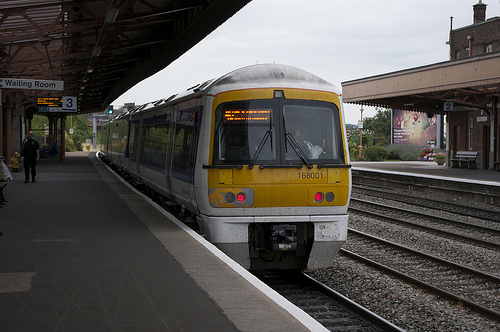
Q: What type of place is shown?
A: It is a station.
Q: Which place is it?
A: It is a station.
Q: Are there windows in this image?
A: Yes, there is a window.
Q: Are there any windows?
A: Yes, there is a window.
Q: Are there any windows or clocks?
A: Yes, there is a window.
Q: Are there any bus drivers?
A: No, there are no bus drivers.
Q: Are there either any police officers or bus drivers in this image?
A: No, there are no bus drivers or police officers.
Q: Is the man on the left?
A: Yes, the man is on the left of the image.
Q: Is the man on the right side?
A: No, the man is on the left of the image.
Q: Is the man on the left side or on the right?
A: The man is on the left of the image.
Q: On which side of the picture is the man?
A: The man is on the left of the image.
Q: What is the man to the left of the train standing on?
A: The man is standing on the platform.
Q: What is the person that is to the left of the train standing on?
A: The man is standing on the platform.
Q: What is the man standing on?
A: The man is standing on the platform.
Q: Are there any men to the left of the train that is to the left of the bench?
A: Yes, there is a man to the left of the train.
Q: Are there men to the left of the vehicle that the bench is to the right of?
A: Yes, there is a man to the left of the train.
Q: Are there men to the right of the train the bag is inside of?
A: No, the man is to the left of the train.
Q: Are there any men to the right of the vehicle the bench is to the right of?
A: No, the man is to the left of the train.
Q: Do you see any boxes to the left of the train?
A: No, there is a man to the left of the train.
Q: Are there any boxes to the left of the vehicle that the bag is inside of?
A: No, there is a man to the left of the train.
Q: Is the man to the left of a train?
A: Yes, the man is to the left of a train.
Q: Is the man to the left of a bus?
A: No, the man is to the left of a train.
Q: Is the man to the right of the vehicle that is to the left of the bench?
A: No, the man is to the left of the train.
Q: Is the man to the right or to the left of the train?
A: The man is to the left of the train.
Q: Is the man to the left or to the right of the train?
A: The man is to the left of the train.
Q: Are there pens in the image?
A: No, there are no pens.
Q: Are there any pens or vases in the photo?
A: No, there are no pens or vases.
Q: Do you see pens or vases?
A: No, there are no pens or vases.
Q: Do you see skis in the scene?
A: No, there are no skis.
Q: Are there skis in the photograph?
A: No, there are no skis.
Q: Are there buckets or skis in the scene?
A: No, there are no skis or buckets.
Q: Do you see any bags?
A: Yes, there is a bag.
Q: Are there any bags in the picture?
A: Yes, there is a bag.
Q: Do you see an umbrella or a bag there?
A: Yes, there is a bag.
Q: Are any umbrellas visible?
A: No, there are no umbrellas.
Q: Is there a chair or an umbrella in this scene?
A: No, there are no umbrellas or chairs.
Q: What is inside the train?
A: The bag is inside the train.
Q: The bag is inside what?
A: The bag is inside the train.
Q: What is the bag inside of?
A: The bag is inside the train.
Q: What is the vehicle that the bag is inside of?
A: The vehicle is a train.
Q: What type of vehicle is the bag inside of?
A: The bag is inside the train.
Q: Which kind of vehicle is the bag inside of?
A: The bag is inside the train.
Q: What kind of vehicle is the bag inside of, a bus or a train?
A: The bag is inside a train.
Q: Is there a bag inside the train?
A: Yes, there is a bag inside the train.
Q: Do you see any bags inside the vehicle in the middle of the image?
A: Yes, there is a bag inside the train.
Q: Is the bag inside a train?
A: Yes, the bag is inside a train.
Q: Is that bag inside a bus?
A: No, the bag is inside a train.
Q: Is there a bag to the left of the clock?
A: Yes, there is a bag to the left of the clock.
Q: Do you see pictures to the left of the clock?
A: No, there is a bag to the left of the clock.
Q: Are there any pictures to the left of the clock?
A: No, there is a bag to the left of the clock.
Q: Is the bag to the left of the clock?
A: Yes, the bag is to the left of the clock.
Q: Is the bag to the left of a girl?
A: No, the bag is to the left of the clock.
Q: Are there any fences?
A: No, there are no fences.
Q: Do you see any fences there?
A: No, there are no fences.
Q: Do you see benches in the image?
A: Yes, there is a bench.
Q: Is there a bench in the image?
A: Yes, there is a bench.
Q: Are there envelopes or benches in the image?
A: Yes, there is a bench.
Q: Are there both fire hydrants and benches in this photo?
A: No, there is a bench but no fire hydrants.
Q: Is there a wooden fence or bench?
A: Yes, there is a wood bench.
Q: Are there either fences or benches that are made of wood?
A: Yes, the bench is made of wood.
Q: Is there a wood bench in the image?
A: Yes, there is a wood bench.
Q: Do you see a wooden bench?
A: Yes, there is a wood bench.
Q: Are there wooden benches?
A: Yes, there is a wood bench.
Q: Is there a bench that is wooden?
A: Yes, there is a bench that is wooden.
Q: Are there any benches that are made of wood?
A: Yes, there is a bench that is made of wood.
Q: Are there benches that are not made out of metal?
A: Yes, there is a bench that is made of wood.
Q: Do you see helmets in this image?
A: No, there are no helmets.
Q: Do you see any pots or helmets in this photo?
A: No, there are no helmets or pots.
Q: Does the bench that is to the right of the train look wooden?
A: Yes, the bench is wooden.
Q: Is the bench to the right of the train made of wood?
A: Yes, the bench is made of wood.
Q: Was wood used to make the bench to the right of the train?
A: Yes, the bench is made of wood.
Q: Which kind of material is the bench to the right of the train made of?
A: The bench is made of wood.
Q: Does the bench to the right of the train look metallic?
A: No, the bench is wooden.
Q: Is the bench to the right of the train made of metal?
A: No, the bench is made of wood.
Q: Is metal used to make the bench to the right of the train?
A: No, the bench is made of wood.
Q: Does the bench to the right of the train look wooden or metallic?
A: The bench is wooden.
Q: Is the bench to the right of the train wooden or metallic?
A: The bench is wooden.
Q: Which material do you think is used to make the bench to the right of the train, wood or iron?
A: The bench is made of wood.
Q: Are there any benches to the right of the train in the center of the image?
A: Yes, there is a bench to the right of the train.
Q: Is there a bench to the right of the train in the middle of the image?
A: Yes, there is a bench to the right of the train.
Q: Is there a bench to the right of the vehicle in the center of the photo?
A: Yes, there is a bench to the right of the train.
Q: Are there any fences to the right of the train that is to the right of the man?
A: No, there is a bench to the right of the train.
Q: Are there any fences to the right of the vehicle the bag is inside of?
A: No, there is a bench to the right of the train.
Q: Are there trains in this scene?
A: Yes, there is a train.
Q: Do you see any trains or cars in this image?
A: Yes, there is a train.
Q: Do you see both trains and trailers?
A: No, there is a train but no trailers.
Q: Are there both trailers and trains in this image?
A: No, there is a train but no trailers.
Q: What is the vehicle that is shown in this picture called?
A: The vehicle is a train.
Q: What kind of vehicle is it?
A: The vehicle is a train.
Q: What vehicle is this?
A: This is a train.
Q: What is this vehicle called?
A: This is a train.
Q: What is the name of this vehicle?
A: This is a train.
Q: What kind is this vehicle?
A: This is a train.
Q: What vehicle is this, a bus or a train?
A: This is a train.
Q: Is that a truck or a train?
A: That is a train.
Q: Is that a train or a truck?
A: That is a train.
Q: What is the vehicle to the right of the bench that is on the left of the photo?
A: The vehicle is a train.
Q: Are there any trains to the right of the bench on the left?
A: Yes, there is a train to the right of the bench.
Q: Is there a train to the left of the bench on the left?
A: No, the train is to the right of the bench.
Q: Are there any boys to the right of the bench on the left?
A: No, there is a train to the right of the bench.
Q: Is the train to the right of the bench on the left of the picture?
A: Yes, the train is to the right of the bench.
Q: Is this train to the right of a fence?
A: No, the train is to the right of the bench.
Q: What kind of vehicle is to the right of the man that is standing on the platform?
A: The vehicle is a train.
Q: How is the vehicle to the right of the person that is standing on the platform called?
A: The vehicle is a train.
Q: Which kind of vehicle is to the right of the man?
A: The vehicle is a train.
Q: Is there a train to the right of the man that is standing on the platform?
A: Yes, there is a train to the right of the man.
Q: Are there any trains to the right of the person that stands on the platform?
A: Yes, there is a train to the right of the man.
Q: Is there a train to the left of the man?
A: No, the train is to the right of the man.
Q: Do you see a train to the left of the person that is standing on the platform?
A: No, the train is to the right of the man.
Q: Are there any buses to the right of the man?
A: No, there is a train to the right of the man.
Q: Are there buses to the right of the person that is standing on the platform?
A: No, there is a train to the right of the man.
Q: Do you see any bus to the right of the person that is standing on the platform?
A: No, there is a train to the right of the man.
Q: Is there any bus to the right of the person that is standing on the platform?
A: No, there is a train to the right of the man.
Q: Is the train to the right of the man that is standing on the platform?
A: Yes, the train is to the right of the man.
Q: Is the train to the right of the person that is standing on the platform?
A: Yes, the train is to the right of the man.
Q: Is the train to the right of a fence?
A: No, the train is to the right of the man.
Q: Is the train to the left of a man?
A: No, the train is to the right of a man.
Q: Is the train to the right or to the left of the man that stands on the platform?
A: The train is to the right of the man.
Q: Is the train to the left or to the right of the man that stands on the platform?
A: The train is to the right of the man.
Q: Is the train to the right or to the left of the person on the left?
A: The train is to the right of the man.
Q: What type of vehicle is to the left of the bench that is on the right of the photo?
A: The vehicle is a train.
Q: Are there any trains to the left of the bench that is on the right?
A: Yes, there is a train to the left of the bench.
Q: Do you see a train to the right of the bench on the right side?
A: No, the train is to the left of the bench.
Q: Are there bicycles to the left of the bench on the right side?
A: No, there is a train to the left of the bench.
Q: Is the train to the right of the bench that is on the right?
A: No, the train is to the left of the bench.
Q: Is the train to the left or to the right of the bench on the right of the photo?
A: The train is to the left of the bench.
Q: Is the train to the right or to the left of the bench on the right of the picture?
A: The train is to the left of the bench.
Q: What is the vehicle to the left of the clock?
A: The vehicle is a train.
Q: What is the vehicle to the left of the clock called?
A: The vehicle is a train.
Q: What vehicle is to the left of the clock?
A: The vehicle is a train.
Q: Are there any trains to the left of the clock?
A: Yes, there is a train to the left of the clock.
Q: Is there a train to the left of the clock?
A: Yes, there is a train to the left of the clock.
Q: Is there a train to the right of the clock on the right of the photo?
A: No, the train is to the left of the clock.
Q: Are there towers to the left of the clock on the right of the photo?
A: No, there is a train to the left of the clock.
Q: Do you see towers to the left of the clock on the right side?
A: No, there is a train to the left of the clock.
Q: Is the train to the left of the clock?
A: Yes, the train is to the left of the clock.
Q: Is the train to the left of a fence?
A: No, the train is to the left of the clock.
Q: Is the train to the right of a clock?
A: No, the train is to the left of a clock.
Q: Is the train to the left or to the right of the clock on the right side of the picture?
A: The train is to the left of the clock.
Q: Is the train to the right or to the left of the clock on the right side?
A: The train is to the left of the clock.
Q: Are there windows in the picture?
A: Yes, there is a window.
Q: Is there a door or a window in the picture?
A: Yes, there is a window.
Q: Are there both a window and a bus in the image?
A: No, there is a window but no buses.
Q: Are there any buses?
A: No, there are no buses.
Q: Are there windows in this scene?
A: Yes, there is a window.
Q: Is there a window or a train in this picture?
A: Yes, there is a window.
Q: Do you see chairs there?
A: No, there are no chairs.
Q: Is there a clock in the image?
A: Yes, there is a clock.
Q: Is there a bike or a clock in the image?
A: Yes, there is a clock.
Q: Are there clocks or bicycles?
A: Yes, there is a clock.